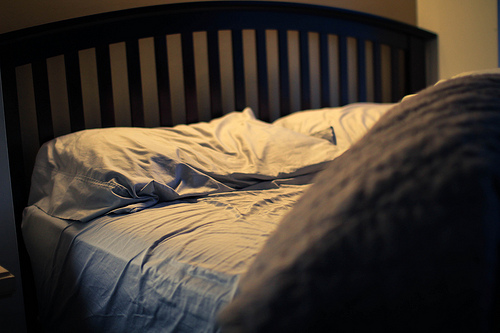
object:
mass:
[205, 73, 497, 331]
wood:
[201, 20, 293, 111]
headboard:
[0, 0, 437, 232]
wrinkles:
[98, 128, 306, 262]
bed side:
[26, 206, 231, 326]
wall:
[435, 1, 499, 83]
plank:
[95, 33, 120, 128]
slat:
[242, 27, 262, 119]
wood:
[24, 35, 104, 133]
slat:
[136, 42, 162, 127]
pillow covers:
[28, 108, 346, 224]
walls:
[4, 1, 396, 105]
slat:
[108, 35, 129, 116]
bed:
[2, 2, 439, 331]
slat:
[178, 32, 198, 124]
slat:
[276, 22, 291, 118]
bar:
[206, 25, 227, 117]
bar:
[153, 33, 172, 125]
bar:
[178, 27, 202, 119]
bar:
[297, 33, 310, 110]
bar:
[125, 34, 147, 126]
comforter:
[32, 102, 497, 331]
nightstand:
[0, 260, 28, 330]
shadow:
[22, 243, 81, 331]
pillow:
[272, 104, 401, 178]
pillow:
[31, 106, 341, 226]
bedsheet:
[21, 169, 319, 330]